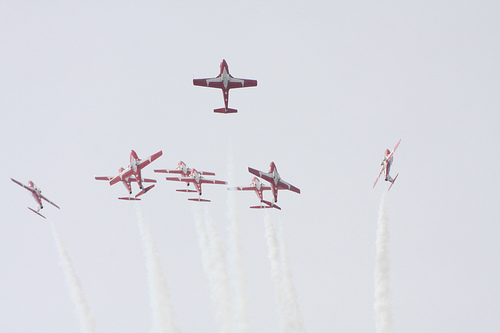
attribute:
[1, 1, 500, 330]
sky — behind plane, grey, bright, clear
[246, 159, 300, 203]
airplane — red, white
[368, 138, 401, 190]
plane — mid roll, red, white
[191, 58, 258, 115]
plane — red, white, vertical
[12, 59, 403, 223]
planes — performing a stunt, red, white, flying high, flying close togethe, flying, a stream, turbo prop airplanes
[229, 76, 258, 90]
airplane wing — red, white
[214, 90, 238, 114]
tail section of plan — red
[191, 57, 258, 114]
side of airplane — underside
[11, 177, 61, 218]
plane — mid roll, to the side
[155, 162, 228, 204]
plane — parallel